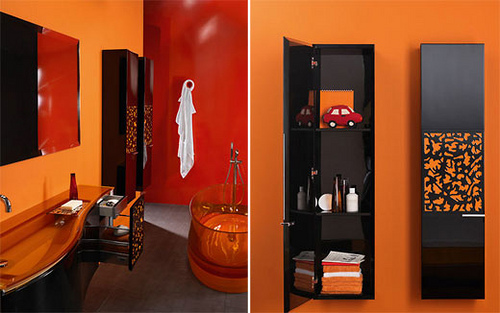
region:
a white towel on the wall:
[177, 79, 204, 174]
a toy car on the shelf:
[321, 97, 361, 129]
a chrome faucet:
[221, 133, 245, 213]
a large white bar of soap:
[61, 191, 87, 215]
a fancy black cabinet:
[101, 40, 167, 189]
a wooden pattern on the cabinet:
[426, 135, 481, 214]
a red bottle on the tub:
[61, 168, 81, 198]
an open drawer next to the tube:
[99, 194, 127, 219]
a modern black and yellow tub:
[6, 177, 96, 310]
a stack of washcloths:
[320, 258, 365, 298]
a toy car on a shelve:
[320, 105, 361, 137]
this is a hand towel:
[166, 69, 208, 184]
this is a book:
[323, 248, 367, 266]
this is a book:
[316, 263, 361, 271]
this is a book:
[324, 270, 366, 279]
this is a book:
[319, 276, 363, 283]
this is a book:
[318, 280, 370, 285]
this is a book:
[316, 285, 368, 291]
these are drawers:
[94, 180, 165, 270]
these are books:
[314, 248, 383, 310]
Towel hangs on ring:
[174, 77, 197, 178]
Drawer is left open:
[93, 187, 144, 271]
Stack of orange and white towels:
[317, 264, 365, 296]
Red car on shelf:
[319, 103, 362, 128]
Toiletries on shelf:
[311, 173, 361, 213]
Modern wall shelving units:
[100, 48, 153, 203]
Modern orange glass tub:
[187, 142, 248, 296]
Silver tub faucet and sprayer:
[224, 140, 245, 187]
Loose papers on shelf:
[321, 251, 366, 265]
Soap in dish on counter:
[44, 196, 89, 216]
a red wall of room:
[145, 2, 243, 205]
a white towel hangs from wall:
[164, 69, 210, 182]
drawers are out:
[48, 161, 155, 278]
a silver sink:
[1, 190, 20, 220]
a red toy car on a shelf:
[313, 95, 364, 135]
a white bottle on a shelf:
[338, 184, 362, 214]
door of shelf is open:
[266, 28, 381, 312]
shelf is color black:
[277, 30, 385, 311]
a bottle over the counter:
[59, 163, 88, 200]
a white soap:
[48, 195, 88, 218]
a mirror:
[41, 36, 84, 147]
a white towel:
[171, 90, 197, 179]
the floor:
[122, 268, 191, 307]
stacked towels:
[324, 264, 364, 290]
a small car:
[323, 103, 364, 127]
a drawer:
[99, 211, 150, 266]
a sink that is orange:
[6, 232, 56, 262]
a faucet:
[3, 187, 14, 218]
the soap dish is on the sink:
[51, 195, 82, 211]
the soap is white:
[64, 196, 79, 211]